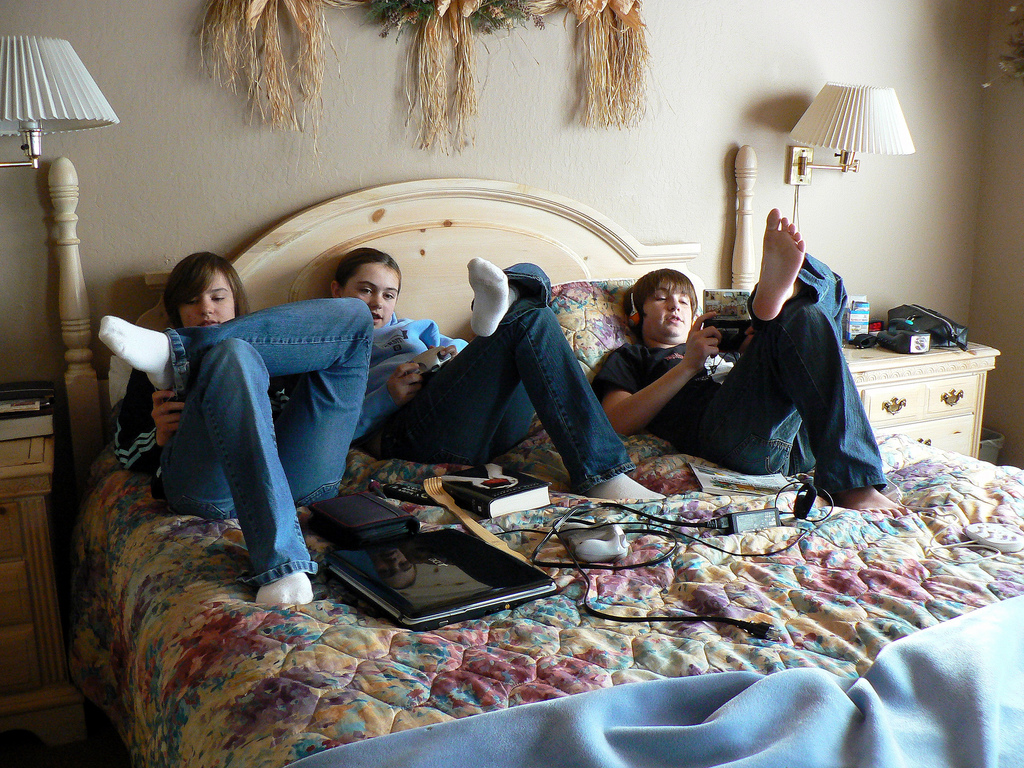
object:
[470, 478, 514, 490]
hand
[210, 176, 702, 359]
headboard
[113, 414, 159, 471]
stripes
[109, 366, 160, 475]
sleeve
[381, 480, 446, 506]
control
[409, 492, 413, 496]
buttons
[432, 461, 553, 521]
book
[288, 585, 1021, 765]
blanket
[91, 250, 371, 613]
kid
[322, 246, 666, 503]
kid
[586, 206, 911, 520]
kid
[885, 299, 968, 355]
bag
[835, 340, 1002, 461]
table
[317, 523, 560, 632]
laptop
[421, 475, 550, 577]
back scratcher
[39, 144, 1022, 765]
bed